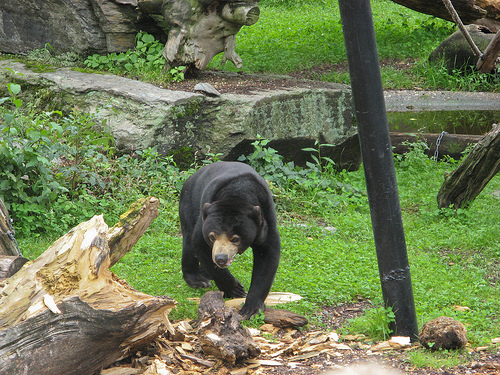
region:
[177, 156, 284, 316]
A black bear cab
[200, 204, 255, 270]
The white snout of a bear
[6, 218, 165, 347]
A piece of log with scratch marks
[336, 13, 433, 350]
A black iron pillar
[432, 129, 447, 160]
A piece of chain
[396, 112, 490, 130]
Stagnant water with reflection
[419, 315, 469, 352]
A piece of rock on the ground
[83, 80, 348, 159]
A big layer of rock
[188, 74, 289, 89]
Soil lying on the rock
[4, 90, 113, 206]
Vegetation growing by the rock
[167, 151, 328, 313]
black bear is walking on ground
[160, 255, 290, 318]
black paws are on green grass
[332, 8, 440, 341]
tall black pole to right of bear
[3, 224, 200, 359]
light brown and downed tree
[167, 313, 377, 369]
wood chips in front of bear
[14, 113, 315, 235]
green and leafy bushes are behind bear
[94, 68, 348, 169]
grey stone ledge is behind boy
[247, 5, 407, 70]
tall green grasses in background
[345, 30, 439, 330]
black metal pole is near wood chips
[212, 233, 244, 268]
bear has dark brown nose and ears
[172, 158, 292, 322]
One bear is walking.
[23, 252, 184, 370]
Logs are brown color.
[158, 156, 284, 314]
Bear is black color.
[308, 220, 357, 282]
Grass are green color.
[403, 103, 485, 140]
Water is green color.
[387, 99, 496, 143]
Reflection is seen in water.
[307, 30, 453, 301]
Pole is grey color.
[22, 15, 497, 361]
Day time picture.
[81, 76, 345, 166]
Rock is grey color.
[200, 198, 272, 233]
Bear has two small ears.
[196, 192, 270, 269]
a head of a bear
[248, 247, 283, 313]
the leg of a bear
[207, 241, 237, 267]
the nose of a bear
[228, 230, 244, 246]
the eye of a bear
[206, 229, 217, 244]
the eye of a bear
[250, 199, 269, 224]
an ear of a bear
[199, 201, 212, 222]
an ear of a bear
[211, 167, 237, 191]
the fur of a bear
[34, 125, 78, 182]
the leaves of weeds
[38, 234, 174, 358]
a dead tree trunk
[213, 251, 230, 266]
Nose of a black bear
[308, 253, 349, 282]
Green grass beneath the bear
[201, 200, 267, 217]
Ears on the black bear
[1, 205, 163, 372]
Large piece of wood next to the bear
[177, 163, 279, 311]
Black bear on the grass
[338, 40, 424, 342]
Pole sticking out of the ground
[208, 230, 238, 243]
Eyes of the bear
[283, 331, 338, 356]
Wood shavings on the ground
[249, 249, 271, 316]
Front leg of the bear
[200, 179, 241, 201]
Black fur on the bear